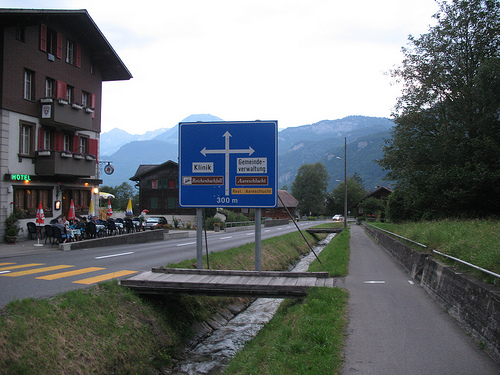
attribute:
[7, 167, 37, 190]
sign — green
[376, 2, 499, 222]
tree — tall 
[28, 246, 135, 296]
markings — yellow